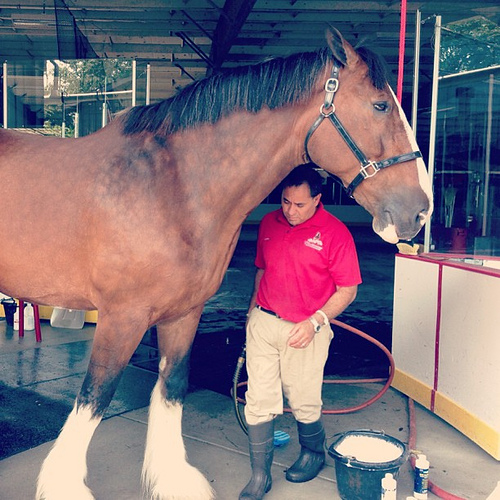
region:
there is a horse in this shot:
[26, 46, 439, 491]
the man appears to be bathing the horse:
[239, 176, 432, 498]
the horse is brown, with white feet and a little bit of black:
[18, 120, 338, 497]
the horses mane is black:
[133, 55, 328, 125]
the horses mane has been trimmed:
[116, 35, 403, 130]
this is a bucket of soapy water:
[323, 399, 423, 492]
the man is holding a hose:
[221, 255, 367, 424]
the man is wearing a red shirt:
[253, 210, 354, 321]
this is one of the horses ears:
[318, 23, 368, 81]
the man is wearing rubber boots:
[231, 415, 341, 497]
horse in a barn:
[1, 34, 433, 499]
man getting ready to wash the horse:
[238, 165, 360, 495]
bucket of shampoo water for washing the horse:
[337, 428, 417, 498]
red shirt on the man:
[250, 206, 353, 327]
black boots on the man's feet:
[237, 419, 324, 499]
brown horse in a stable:
[0, 25, 437, 497]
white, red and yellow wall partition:
[390, 244, 499, 459]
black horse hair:
[124, 44, 386, 135]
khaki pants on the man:
[245, 310, 336, 421]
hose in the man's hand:
[237, 302, 398, 447]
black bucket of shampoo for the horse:
[336, 430, 400, 472]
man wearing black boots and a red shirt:
[280, 172, 325, 470]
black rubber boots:
[241, 415, 324, 498]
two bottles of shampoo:
[381, 452, 430, 497]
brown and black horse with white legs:
[0, 27, 430, 494]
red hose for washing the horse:
[335, 319, 405, 424]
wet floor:
[3, 344, 64, 412]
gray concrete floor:
[101, 425, 134, 492]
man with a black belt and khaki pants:
[266, 171, 338, 331]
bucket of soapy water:
[329, 430, 403, 497]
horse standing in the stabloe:
[2, 23, 447, 495]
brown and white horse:
[0, 20, 425, 499]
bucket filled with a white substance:
[319, 423, 404, 499]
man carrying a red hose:
[229, 163, 402, 498]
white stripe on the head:
[385, 81, 442, 218]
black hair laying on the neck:
[117, 52, 336, 136]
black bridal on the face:
[301, 57, 446, 236]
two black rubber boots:
[227, 417, 329, 499]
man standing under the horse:
[241, 163, 373, 496]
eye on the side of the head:
[368, 96, 390, 117]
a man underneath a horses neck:
[226, 154, 363, 498]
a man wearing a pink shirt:
[233, 153, 366, 498]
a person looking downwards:
[271, 169, 335, 236]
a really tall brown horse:
[0, 22, 436, 497]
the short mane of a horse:
[121, 40, 393, 137]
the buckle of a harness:
[319, 76, 340, 116]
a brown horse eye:
[366, 98, 393, 115]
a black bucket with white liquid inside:
[321, 423, 407, 497]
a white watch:
[309, 311, 320, 335]